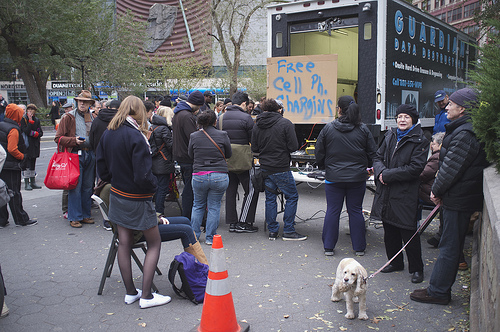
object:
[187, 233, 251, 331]
cone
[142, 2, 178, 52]
tarp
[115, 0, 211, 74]
structure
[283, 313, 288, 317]
leaves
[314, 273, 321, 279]
leaves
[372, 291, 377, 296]
leaves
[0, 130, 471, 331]
ground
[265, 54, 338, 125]
sign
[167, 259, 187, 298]
straps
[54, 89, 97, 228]
man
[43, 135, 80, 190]
bag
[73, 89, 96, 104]
hat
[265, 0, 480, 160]
truck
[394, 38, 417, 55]
lettering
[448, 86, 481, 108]
hat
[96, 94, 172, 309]
woman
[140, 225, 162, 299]
black nylon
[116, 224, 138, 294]
black nylon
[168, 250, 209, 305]
backpack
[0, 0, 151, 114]
tree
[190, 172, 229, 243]
jeans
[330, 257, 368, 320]
dog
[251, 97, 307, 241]
people standing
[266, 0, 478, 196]
cellphone charging-station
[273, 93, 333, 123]
chargers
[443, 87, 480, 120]
head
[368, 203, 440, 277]
leash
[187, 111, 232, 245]
woman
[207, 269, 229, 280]
strips